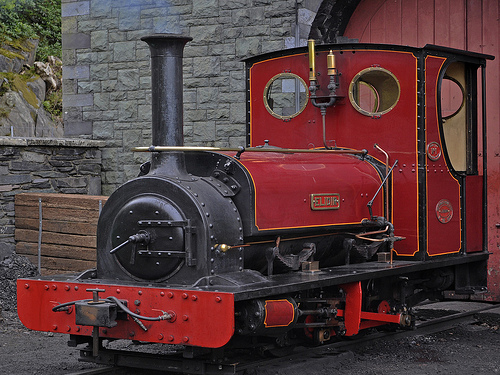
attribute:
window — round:
[262, 71, 309, 118]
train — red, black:
[16, 34, 496, 373]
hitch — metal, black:
[51, 287, 171, 357]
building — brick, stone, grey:
[58, 23, 286, 156]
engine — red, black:
[1, 12, 495, 354]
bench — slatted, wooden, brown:
[11, 190, 109, 267]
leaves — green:
[2, 3, 61, 71]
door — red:
[416, 45, 486, 256]